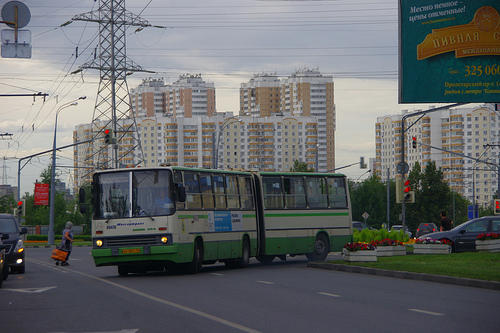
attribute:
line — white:
[23, 255, 259, 330]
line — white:
[32, 258, 265, 329]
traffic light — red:
[101, 126, 111, 144]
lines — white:
[312, 286, 341, 302]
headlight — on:
[93, 237, 103, 249]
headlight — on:
[162, 233, 169, 242]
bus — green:
[92, 166, 353, 271]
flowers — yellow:
[359, 224, 413, 242]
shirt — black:
[439, 217, 451, 229]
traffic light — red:
[101, 128, 110, 144]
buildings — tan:
[144, 79, 329, 162]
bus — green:
[84, 159, 359, 277]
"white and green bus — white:
[85, 163, 361, 263]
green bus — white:
[167, 216, 273, 283]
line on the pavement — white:
[143, 279, 225, 332]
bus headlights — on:
[78, 231, 175, 249]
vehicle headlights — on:
[13, 244, 35, 271]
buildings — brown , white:
[56, 73, 342, 196]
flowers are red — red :
[343, 239, 374, 254]